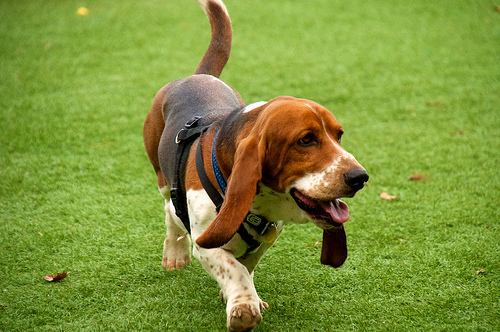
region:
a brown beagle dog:
[142, 1, 370, 329]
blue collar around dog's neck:
[209, 128, 226, 195]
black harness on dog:
[168, 113, 271, 263]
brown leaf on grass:
[39, 268, 69, 285]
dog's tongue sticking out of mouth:
[317, 196, 352, 227]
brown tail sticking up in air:
[199, 1, 232, 79]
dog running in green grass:
[0, 0, 499, 329]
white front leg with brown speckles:
[187, 196, 270, 327]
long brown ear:
[193, 133, 271, 249]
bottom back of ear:
[317, 226, 349, 268]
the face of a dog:
[265, 97, 367, 232]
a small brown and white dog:
[134, 1, 371, 331]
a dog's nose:
[341, 162, 368, 190]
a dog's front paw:
[224, 299, 262, 329]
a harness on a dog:
[167, 115, 274, 262]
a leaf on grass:
[41, 269, 71, 284]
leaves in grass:
[375, 162, 433, 208]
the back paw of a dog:
[161, 237, 193, 270]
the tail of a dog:
[197, 0, 233, 77]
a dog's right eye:
[295, 130, 317, 145]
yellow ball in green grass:
[69, 4, 98, 31]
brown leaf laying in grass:
[11, 250, 96, 295]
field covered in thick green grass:
[36, 129, 130, 221]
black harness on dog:
[163, 110, 207, 207]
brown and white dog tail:
[165, 0, 260, 77]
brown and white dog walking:
[109, 0, 400, 325]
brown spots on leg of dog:
[212, 258, 254, 296]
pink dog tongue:
[305, 190, 358, 227]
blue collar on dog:
[210, 124, 236, 196]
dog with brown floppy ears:
[113, 26, 408, 327]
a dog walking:
[117, 1, 367, 327]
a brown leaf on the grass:
[37, 268, 68, 282]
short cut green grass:
[1, 0, 498, 327]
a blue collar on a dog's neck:
[210, 124, 251, 213]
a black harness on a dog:
[166, 101, 265, 269]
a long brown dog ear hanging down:
[197, 130, 263, 254]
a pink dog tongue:
[327, 191, 354, 220]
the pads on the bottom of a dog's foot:
[226, 309, 262, 330]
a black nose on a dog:
[346, 168, 371, 183]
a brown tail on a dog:
[194, 0, 241, 74]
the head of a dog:
[253, 91, 373, 231]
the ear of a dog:
[192, 130, 269, 250]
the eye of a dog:
[296, 128, 323, 153]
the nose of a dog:
[339, 165, 373, 192]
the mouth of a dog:
[288, 182, 355, 230]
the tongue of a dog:
[319, 195, 352, 225]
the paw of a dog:
[228, 295, 275, 330]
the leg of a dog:
[181, 205, 258, 293]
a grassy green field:
[1, 0, 499, 330]